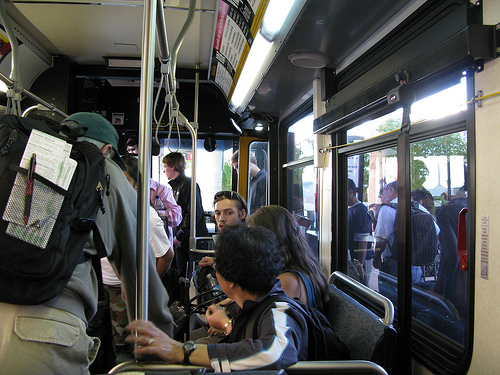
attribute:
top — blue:
[272, 267, 320, 324]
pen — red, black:
[22, 152, 35, 225]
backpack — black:
[0, 112, 106, 306]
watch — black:
[182, 341, 195, 363]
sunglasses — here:
[212, 192, 244, 202]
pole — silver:
[134, 0, 157, 319]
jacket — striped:
[206, 281, 307, 374]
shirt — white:
[374, 197, 397, 281]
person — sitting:
[196, 297, 240, 340]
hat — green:
[60, 111, 128, 159]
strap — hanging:
[153, 61, 175, 128]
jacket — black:
[167, 175, 191, 257]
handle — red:
[455, 207, 468, 271]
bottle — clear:
[205, 271, 221, 297]